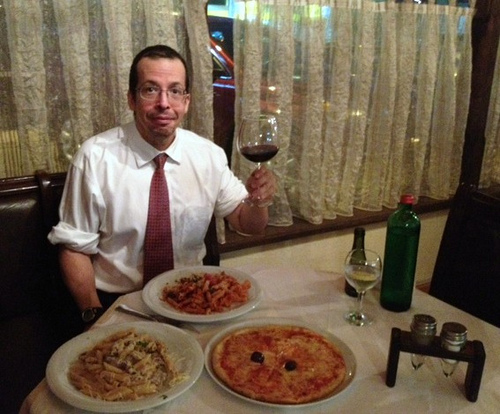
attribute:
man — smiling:
[49, 42, 274, 327]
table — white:
[21, 261, 499, 413]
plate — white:
[205, 316, 363, 410]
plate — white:
[138, 263, 266, 323]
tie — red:
[138, 152, 177, 285]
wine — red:
[242, 142, 278, 162]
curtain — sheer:
[0, 1, 475, 238]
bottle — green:
[378, 192, 425, 315]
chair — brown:
[421, 177, 498, 335]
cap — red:
[396, 189, 418, 208]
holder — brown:
[377, 321, 487, 404]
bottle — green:
[341, 220, 368, 300]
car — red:
[203, 16, 305, 161]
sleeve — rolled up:
[49, 167, 106, 257]